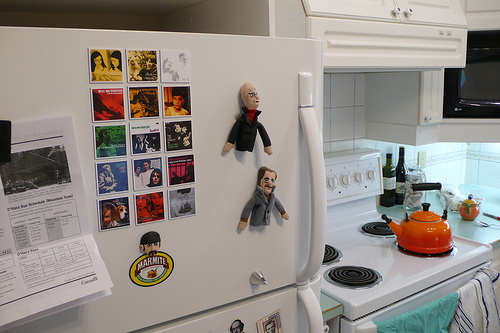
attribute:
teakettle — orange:
[362, 172, 456, 272]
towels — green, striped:
[377, 278, 465, 333]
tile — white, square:
[329, 100, 358, 140]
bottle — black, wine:
[392, 140, 411, 210]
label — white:
[393, 177, 410, 200]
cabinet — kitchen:
[276, 3, 489, 70]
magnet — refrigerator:
[125, 230, 182, 285]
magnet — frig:
[224, 75, 278, 162]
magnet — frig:
[246, 166, 296, 249]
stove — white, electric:
[322, 147, 480, 330]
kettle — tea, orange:
[378, 170, 460, 260]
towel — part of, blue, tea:
[372, 290, 488, 328]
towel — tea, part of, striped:
[367, 298, 463, 331]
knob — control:
[333, 163, 353, 195]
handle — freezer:
[293, 69, 339, 290]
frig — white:
[1, 17, 345, 330]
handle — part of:
[295, 260, 335, 331]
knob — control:
[367, 169, 377, 186]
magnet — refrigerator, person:
[251, 162, 296, 241]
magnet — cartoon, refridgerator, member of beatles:
[130, 233, 186, 291]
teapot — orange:
[390, 166, 462, 280]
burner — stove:
[399, 240, 453, 263]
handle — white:
[293, 62, 357, 299]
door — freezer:
[0, 20, 336, 322]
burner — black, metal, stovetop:
[327, 260, 391, 305]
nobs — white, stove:
[327, 167, 387, 191]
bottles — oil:
[383, 140, 414, 211]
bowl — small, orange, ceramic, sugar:
[458, 186, 486, 233]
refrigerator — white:
[3, 19, 328, 324]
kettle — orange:
[389, 174, 458, 269]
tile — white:
[353, 71, 363, 106]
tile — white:
[330, 72, 355, 106]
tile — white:
[322, 72, 331, 108]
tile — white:
[330, 107, 355, 140]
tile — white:
[353, 105, 367, 137]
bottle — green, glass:
[379, 150, 396, 206]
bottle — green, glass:
[395, 145, 406, 204]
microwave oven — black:
[442, 30, 484, 119]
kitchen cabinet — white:
[302, 1, 469, 27]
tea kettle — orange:
[380, 180, 456, 255]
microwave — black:
[442, 30, 484, 120]